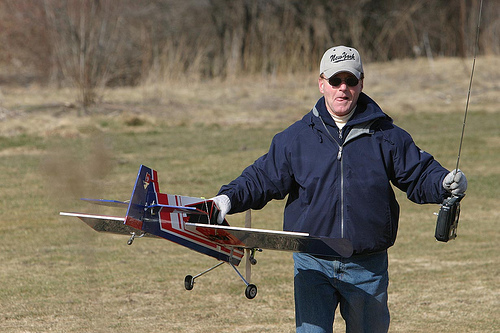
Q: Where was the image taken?
A: It was taken at the field.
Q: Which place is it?
A: It is a field.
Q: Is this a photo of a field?
A: Yes, it is showing a field.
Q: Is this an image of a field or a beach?
A: It is showing a field.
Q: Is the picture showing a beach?
A: No, the picture is showing a field.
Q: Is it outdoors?
A: Yes, it is outdoors.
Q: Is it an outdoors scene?
A: Yes, it is outdoors.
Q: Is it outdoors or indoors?
A: It is outdoors.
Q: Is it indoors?
A: No, it is outdoors.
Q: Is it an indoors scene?
A: No, it is outdoors.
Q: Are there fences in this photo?
A: No, there are no fences.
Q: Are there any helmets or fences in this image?
A: No, there are no fences or helmets.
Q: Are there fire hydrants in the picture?
A: No, there are no fire hydrants.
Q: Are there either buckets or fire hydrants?
A: No, there are no fire hydrants or buckets.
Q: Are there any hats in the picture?
A: Yes, there is a hat.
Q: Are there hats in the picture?
A: Yes, there is a hat.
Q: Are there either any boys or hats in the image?
A: Yes, there is a hat.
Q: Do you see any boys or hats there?
A: Yes, there is a hat.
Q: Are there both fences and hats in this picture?
A: No, there is a hat but no fences.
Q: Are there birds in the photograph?
A: No, there are no birds.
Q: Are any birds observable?
A: No, there are no birds.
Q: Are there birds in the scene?
A: No, there are no birds.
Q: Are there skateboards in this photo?
A: No, there are no skateboards.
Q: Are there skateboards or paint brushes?
A: No, there are no skateboards or paint brushes.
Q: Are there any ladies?
A: No, there are no ladies.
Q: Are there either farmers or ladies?
A: No, there are no ladies or farmers.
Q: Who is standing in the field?
A: The man is standing in the field.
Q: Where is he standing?
A: The man is standing in the field.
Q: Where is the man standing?
A: The man is standing in the field.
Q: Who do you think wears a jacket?
A: The man wears a jacket.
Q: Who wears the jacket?
A: The man wears a jacket.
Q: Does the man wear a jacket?
A: Yes, the man wears a jacket.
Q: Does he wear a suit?
A: No, the man wears a jacket.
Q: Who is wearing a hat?
A: The man is wearing a hat.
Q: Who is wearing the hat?
A: The man is wearing a hat.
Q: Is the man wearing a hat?
A: Yes, the man is wearing a hat.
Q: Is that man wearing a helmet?
A: No, the man is wearing a hat.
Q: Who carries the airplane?
A: The man carries the airplane.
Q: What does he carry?
A: The man carries a plane.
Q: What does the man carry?
A: The man carries a plane.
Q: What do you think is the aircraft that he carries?
A: The aircraft is an airplane.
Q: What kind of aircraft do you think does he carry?
A: The man carries an airplane.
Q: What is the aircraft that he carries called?
A: The aircraft is an airplane.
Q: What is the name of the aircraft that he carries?
A: The aircraft is an airplane.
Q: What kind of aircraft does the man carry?
A: The man carries an airplane.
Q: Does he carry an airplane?
A: Yes, the man carries an airplane.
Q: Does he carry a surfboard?
A: No, the man carries an airplane.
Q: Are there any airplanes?
A: Yes, there is an airplane.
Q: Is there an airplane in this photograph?
A: Yes, there is an airplane.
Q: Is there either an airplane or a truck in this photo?
A: Yes, there is an airplane.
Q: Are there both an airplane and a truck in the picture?
A: No, there is an airplane but no trucks.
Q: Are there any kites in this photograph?
A: No, there are no kites.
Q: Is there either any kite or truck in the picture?
A: No, there are no kites or trucks.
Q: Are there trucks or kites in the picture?
A: No, there are no kites or trucks.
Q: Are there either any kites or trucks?
A: No, there are no kites or trucks.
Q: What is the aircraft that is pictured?
A: The aircraft is an airplane.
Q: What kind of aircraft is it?
A: The aircraft is an airplane.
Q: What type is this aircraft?
A: This is an airplane.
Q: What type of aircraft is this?
A: This is an airplane.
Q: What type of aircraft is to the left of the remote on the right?
A: The aircraft is an airplane.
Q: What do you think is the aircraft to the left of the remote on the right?
A: The aircraft is an airplane.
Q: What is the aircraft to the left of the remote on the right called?
A: The aircraft is an airplane.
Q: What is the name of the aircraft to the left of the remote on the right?
A: The aircraft is an airplane.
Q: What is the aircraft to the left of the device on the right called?
A: The aircraft is an airplane.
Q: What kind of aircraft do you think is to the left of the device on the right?
A: The aircraft is an airplane.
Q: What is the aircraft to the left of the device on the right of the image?
A: The aircraft is an airplane.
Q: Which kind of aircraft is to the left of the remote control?
A: The aircraft is an airplane.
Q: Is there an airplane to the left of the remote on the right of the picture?
A: Yes, there is an airplane to the left of the remote control.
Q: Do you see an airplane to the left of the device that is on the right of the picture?
A: Yes, there is an airplane to the left of the remote control.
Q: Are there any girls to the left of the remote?
A: No, there is an airplane to the left of the remote.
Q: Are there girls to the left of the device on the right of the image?
A: No, there is an airplane to the left of the remote.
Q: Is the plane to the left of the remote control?
A: Yes, the plane is to the left of the remote control.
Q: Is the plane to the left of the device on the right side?
A: Yes, the plane is to the left of the remote control.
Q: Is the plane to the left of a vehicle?
A: No, the plane is to the left of the remote control.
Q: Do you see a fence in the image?
A: No, there are no fences.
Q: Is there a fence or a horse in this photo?
A: No, there are no fences or horses.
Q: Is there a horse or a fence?
A: No, there are no fences or horses.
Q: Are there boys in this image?
A: No, there are no boys.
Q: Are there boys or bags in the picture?
A: No, there are no boys or bags.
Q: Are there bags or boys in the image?
A: No, there are no boys or bags.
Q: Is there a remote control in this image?
A: Yes, there is a remote control.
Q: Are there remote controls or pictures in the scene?
A: Yes, there is a remote control.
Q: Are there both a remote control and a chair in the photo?
A: No, there is a remote control but no chairs.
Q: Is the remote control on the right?
A: Yes, the remote control is on the right of the image.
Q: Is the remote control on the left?
A: No, the remote control is on the right of the image.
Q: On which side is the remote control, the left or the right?
A: The remote control is on the right of the image.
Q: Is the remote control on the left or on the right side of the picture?
A: The remote control is on the right of the image.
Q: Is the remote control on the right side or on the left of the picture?
A: The remote control is on the right of the image.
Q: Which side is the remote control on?
A: The remote control is on the right of the image.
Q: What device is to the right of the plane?
A: The device is a remote control.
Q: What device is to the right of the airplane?
A: The device is a remote control.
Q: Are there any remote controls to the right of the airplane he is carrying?
A: Yes, there is a remote control to the right of the plane.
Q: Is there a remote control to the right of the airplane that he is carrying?
A: Yes, there is a remote control to the right of the plane.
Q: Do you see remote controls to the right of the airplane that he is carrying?
A: Yes, there is a remote control to the right of the plane.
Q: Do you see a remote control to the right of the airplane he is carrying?
A: Yes, there is a remote control to the right of the plane.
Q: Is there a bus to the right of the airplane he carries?
A: No, there is a remote control to the right of the plane.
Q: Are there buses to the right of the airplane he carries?
A: No, there is a remote control to the right of the plane.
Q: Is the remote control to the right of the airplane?
A: Yes, the remote control is to the right of the airplane.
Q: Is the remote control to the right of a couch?
A: No, the remote control is to the right of the airplane.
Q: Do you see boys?
A: No, there are no boys.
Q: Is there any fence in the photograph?
A: No, there are no fences.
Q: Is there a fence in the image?
A: No, there are no fences.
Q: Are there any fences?
A: No, there are no fences.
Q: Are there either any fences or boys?
A: No, there are no fences or boys.